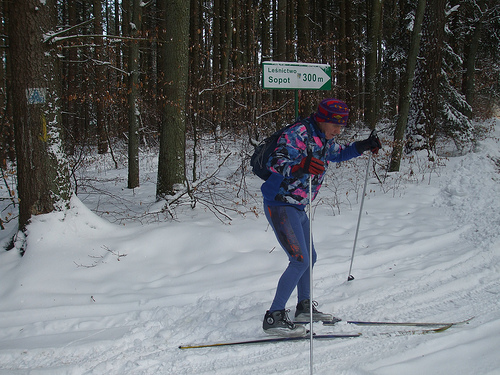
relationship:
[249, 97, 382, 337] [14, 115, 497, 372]
lady skiing in snow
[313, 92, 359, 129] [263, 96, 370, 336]
hat on woman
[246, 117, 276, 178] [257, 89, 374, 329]
backpack on woman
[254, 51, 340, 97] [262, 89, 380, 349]
sign behind woman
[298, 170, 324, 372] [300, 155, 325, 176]
pole in hand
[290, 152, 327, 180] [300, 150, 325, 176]
glove on hand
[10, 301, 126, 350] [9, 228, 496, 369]
tracks are in snow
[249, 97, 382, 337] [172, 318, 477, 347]
lady on skis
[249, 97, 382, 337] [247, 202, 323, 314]
lady wearing pants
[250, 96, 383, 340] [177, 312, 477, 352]
man wearing skis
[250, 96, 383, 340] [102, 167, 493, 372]
man on hill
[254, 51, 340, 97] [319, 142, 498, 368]
sign pointing up hill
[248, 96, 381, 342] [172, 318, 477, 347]
man wearing skis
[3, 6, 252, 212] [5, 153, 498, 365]
trees are on hill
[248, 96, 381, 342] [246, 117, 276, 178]
man wearing backpack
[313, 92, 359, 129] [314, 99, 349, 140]
hat on hat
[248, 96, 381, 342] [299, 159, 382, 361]
man holding poles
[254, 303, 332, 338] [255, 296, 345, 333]
shoes are on man's feet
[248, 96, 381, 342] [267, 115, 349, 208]
man wearing sweater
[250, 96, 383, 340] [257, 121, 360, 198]
man wearing jacket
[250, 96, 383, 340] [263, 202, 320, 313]
man wearing pants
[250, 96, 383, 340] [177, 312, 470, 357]
man wearing skis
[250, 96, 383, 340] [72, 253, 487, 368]
man on snow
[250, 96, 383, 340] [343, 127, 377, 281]
man holding poles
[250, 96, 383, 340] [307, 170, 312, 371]
man holding pole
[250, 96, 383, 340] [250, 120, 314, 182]
man wearing backpack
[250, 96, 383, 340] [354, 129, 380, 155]
man wearing gloves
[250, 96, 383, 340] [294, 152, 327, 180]
man wearing gloves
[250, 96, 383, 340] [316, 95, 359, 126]
man wearing hat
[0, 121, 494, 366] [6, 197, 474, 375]
ground covered in snow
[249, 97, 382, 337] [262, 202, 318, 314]
lady wearing pants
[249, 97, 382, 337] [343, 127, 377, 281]
lady holding poles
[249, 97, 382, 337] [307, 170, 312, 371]
lady holding pole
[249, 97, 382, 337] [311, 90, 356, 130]
lady wearing hat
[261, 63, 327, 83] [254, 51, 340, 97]
arrow in sign